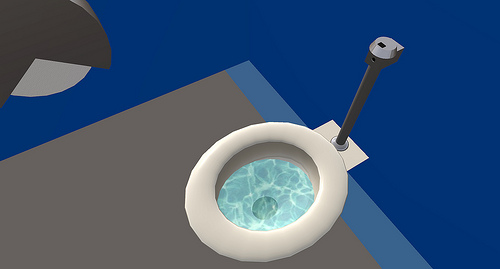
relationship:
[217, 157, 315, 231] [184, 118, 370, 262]
water in toilet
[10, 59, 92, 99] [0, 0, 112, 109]
paper in dispenser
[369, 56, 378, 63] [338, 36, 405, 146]
sensor on post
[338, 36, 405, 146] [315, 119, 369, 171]
post extending from square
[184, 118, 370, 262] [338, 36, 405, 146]
toilet attached to post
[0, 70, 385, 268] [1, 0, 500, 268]
floor in bathroom